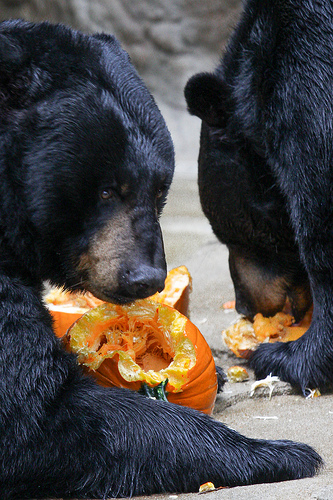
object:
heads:
[182, 69, 316, 327]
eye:
[98, 182, 113, 200]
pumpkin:
[41, 263, 194, 340]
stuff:
[103, 328, 123, 350]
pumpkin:
[309, 388, 321, 403]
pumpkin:
[225, 362, 253, 387]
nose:
[233, 292, 248, 321]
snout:
[118, 212, 167, 297]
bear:
[0, 15, 322, 499]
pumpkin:
[197, 478, 227, 495]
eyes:
[96, 183, 114, 205]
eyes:
[150, 178, 167, 205]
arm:
[0, 283, 260, 499]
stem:
[137, 378, 171, 409]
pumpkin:
[61, 297, 218, 424]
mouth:
[242, 285, 304, 315]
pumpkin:
[221, 300, 236, 312]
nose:
[131, 247, 168, 293]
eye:
[152, 181, 165, 202]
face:
[72, 165, 169, 308]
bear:
[182, 0, 331, 397]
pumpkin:
[222, 312, 320, 361]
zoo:
[0, 1, 331, 498]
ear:
[166, 64, 238, 121]